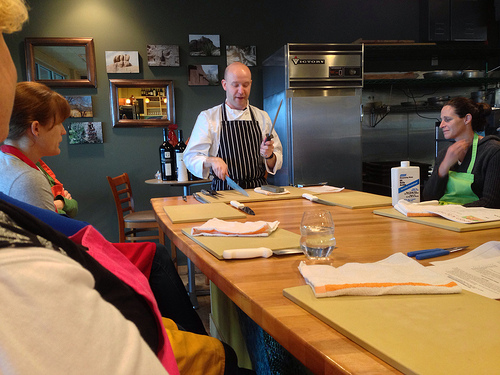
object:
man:
[182, 61, 283, 193]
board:
[196, 186, 321, 203]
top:
[400, 160, 412, 167]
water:
[299, 225, 334, 260]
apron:
[210, 101, 271, 193]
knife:
[262, 99, 285, 145]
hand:
[258, 136, 275, 158]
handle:
[192, 192, 202, 198]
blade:
[260, 97, 284, 147]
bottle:
[299, 209, 336, 265]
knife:
[220, 243, 337, 261]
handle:
[263, 132, 275, 147]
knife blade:
[226, 176, 250, 198]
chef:
[180, 62, 284, 193]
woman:
[420, 98, 500, 208]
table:
[150, 185, 500, 375]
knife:
[219, 173, 250, 198]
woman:
[1, 81, 250, 375]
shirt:
[0, 150, 57, 215]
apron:
[0, 200, 182, 373]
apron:
[436, 133, 477, 206]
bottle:
[172, 129, 192, 181]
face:
[225, 64, 252, 107]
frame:
[23, 35, 99, 87]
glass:
[298, 205, 337, 262]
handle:
[406, 247, 451, 261]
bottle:
[390, 160, 420, 207]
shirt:
[422, 136, 500, 209]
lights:
[124, 98, 130, 104]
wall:
[107, 133, 147, 186]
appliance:
[260, 42, 365, 193]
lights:
[324, 51, 333, 97]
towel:
[296, 251, 463, 298]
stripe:
[314, 281, 456, 295]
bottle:
[158, 128, 177, 182]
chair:
[105, 171, 165, 246]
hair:
[4, 82, 71, 141]